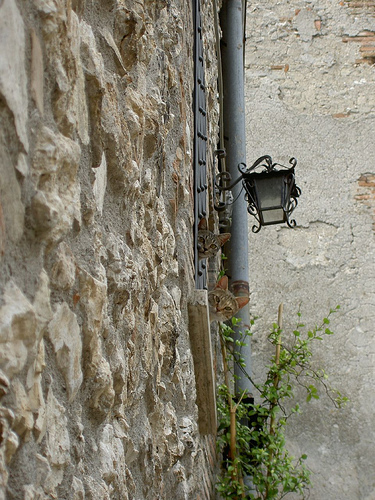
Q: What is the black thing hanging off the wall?
A: Light.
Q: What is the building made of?
A: Rock.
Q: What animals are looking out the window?
A: Cats.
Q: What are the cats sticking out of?
A: Window.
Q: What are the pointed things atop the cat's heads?
A: Ears.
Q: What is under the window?
A: Ledge.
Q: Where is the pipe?
A: Corner.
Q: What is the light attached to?
A: Wall.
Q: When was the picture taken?
A: Daytime.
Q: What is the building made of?
A: Brick.